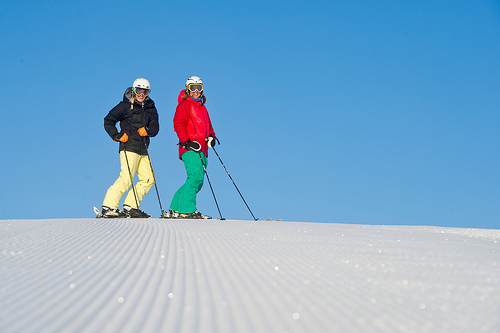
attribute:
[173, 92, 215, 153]
jacket — red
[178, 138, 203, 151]
ski gloves — black, white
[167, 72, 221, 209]
person — skiing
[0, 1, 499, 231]
sky — clear, blue, above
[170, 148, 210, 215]
pants — green, ski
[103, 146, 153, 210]
pants — tan, snow, ski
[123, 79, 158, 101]
goggles — teal, ski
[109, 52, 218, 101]
helmets — white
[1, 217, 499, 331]
snow — white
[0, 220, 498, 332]
hill — snowy, very flat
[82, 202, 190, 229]
skis — black, grey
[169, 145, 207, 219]
pants — green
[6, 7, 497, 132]
sky — blue, clear, behind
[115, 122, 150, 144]
gloves — orange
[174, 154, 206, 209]
pants — teal, snow, ski